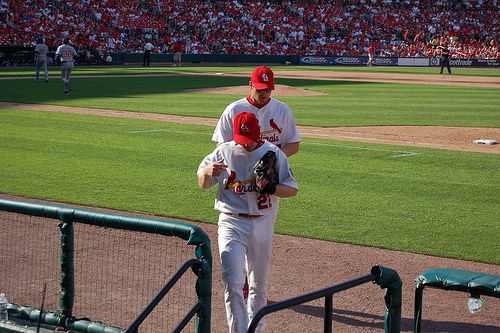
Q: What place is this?
A: It is a field.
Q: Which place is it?
A: It is a field.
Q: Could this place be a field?
A: Yes, it is a field.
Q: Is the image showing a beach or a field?
A: It is showing a field.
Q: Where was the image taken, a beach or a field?
A: It was taken at a field.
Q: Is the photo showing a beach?
A: No, the picture is showing a field.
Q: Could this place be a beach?
A: No, it is a field.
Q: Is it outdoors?
A: Yes, it is outdoors.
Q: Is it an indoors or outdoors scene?
A: It is outdoors.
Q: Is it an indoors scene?
A: No, it is outdoors.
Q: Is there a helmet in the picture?
A: No, there are no helmets.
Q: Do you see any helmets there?
A: No, there are no helmets.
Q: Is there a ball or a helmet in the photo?
A: No, there are no helmets or balls.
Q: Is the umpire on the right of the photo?
A: Yes, the umpire is on the right of the image.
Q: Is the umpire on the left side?
A: No, the umpire is on the right of the image.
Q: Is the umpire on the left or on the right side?
A: The umpire is on the right of the image.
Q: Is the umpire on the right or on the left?
A: The umpire is on the right of the image.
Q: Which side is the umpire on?
A: The umpire is on the right of the image.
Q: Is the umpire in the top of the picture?
A: Yes, the umpire is in the top of the image.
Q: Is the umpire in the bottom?
A: No, the umpire is in the top of the image.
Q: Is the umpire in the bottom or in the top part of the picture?
A: The umpire is in the top of the image.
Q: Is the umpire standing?
A: Yes, the umpire is standing.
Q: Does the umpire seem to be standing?
A: Yes, the umpire is standing.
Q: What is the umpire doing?
A: The umpire is standing.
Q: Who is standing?
A: The umpire is standing.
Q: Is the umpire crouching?
A: No, the umpire is standing.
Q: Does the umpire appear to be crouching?
A: No, the umpire is standing.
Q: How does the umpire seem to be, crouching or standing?
A: The umpire is standing.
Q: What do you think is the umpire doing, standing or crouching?
A: The umpire is standing.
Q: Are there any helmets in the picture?
A: No, there are no helmets.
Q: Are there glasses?
A: No, there are no glasses.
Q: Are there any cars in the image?
A: No, there are no cars.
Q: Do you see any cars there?
A: No, there are no cars.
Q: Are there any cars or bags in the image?
A: No, there are no cars or bags.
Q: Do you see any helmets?
A: No, there are no helmets.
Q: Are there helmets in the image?
A: No, there are no helmets.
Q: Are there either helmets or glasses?
A: No, there are no helmets or glasses.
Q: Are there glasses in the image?
A: No, there are no glasses.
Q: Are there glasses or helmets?
A: No, there are no glasses or helmets.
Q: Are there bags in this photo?
A: No, there are no bags.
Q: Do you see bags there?
A: No, there are no bags.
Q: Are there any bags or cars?
A: No, there are no bags or cars.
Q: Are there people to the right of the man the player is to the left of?
A: Yes, there are people to the right of the man.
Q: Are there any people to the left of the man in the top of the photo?
A: No, the people are to the right of the man.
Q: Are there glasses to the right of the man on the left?
A: No, there are people to the right of the man.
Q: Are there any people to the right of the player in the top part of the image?
A: Yes, there are people to the right of the player.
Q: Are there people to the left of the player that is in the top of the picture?
A: No, the people are to the right of the player.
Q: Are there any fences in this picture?
A: Yes, there is a fence.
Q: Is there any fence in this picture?
A: Yes, there is a fence.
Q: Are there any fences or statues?
A: Yes, there is a fence.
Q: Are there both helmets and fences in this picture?
A: No, there is a fence but no helmets.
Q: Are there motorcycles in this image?
A: No, there are no motorcycles.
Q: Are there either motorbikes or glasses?
A: No, there are no motorbikes or glasses.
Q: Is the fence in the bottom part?
A: No, the fence is in the top of the image.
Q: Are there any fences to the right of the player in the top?
A: Yes, there is a fence to the right of the player.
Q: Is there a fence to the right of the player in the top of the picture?
A: Yes, there is a fence to the right of the player.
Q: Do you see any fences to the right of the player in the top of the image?
A: Yes, there is a fence to the right of the player.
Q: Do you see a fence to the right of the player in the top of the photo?
A: Yes, there is a fence to the right of the player.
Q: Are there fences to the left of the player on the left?
A: No, the fence is to the right of the player.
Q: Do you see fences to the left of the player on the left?
A: No, the fence is to the right of the player.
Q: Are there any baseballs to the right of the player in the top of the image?
A: No, there is a fence to the right of the player.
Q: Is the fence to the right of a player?
A: Yes, the fence is to the right of a player.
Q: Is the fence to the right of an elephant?
A: No, the fence is to the right of a player.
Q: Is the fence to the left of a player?
A: No, the fence is to the right of a player.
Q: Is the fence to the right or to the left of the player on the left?
A: The fence is to the right of the player.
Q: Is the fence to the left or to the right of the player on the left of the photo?
A: The fence is to the right of the player.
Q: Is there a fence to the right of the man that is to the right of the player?
A: Yes, there is a fence to the right of the man.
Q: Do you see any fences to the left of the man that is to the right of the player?
A: No, the fence is to the right of the man.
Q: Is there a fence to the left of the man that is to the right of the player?
A: No, the fence is to the right of the man.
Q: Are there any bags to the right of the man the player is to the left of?
A: No, there is a fence to the right of the man.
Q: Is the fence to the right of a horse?
A: No, the fence is to the right of a man.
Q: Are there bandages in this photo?
A: No, there are no bandages.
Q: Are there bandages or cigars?
A: No, there are no bandages or cigars.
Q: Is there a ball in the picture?
A: No, there are no balls.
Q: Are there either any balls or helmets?
A: No, there are no balls or helmets.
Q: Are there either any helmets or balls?
A: No, there are no balls or helmets.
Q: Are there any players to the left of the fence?
A: Yes, there is a player to the left of the fence.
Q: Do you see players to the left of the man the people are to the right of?
A: Yes, there is a player to the left of the man.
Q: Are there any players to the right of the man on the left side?
A: No, the player is to the left of the man.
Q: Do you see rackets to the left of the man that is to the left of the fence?
A: No, there is a player to the left of the man.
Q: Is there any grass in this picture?
A: Yes, there is grass.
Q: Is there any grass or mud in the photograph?
A: Yes, there is grass.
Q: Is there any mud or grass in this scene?
A: Yes, there is grass.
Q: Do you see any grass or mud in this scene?
A: Yes, there is grass.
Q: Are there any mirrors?
A: No, there are no mirrors.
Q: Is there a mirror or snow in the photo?
A: No, there are no mirrors or snow.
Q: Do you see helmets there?
A: No, there are no helmets.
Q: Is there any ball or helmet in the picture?
A: No, there are no helmets or balls.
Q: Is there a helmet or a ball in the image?
A: No, there are no helmets or balls.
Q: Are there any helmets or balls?
A: No, there are no helmets or balls.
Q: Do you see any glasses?
A: No, there are no glasses.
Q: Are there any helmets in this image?
A: No, there are no helmets.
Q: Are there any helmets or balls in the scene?
A: No, there are no helmets or balls.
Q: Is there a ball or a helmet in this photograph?
A: No, there are no helmets or balls.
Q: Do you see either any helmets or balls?
A: No, there are no helmets or balls.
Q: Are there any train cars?
A: No, there are no train cars.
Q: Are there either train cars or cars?
A: No, there are no train cars or cars.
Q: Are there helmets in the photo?
A: No, there are no helmets.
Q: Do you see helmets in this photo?
A: No, there are no helmets.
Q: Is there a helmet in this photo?
A: No, there are no helmets.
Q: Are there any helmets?
A: No, there are no helmets.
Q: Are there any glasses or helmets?
A: No, there are no helmets or glasses.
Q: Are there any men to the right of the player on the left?
A: Yes, there is a man to the right of the player.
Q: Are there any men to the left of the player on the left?
A: No, the man is to the right of the player.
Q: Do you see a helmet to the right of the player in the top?
A: No, there is a man to the right of the player.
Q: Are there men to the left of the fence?
A: Yes, there is a man to the left of the fence.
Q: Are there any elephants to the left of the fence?
A: No, there is a man to the left of the fence.